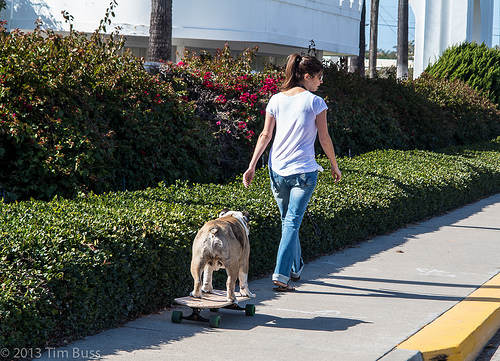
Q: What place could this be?
A: It is a pavement.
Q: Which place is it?
A: It is a pavement.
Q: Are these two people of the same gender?
A: Yes, all the people are female.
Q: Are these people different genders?
A: No, all the people are female.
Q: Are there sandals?
A: Yes, there are sandals.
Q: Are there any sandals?
A: Yes, there are sandals.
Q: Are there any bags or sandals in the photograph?
A: Yes, there are sandals.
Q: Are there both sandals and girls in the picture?
A: Yes, there are both sandals and a girl.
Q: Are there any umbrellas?
A: No, there are no umbrellas.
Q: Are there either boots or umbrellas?
A: No, there are no umbrellas or boots.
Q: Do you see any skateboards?
A: Yes, there is a skateboard.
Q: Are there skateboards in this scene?
A: Yes, there is a skateboard.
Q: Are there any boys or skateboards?
A: Yes, there is a skateboard.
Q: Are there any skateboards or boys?
A: Yes, there is a skateboard.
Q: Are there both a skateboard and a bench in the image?
A: No, there is a skateboard but no benches.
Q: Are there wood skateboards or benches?
A: Yes, there is a wood skateboard.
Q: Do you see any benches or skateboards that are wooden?
A: Yes, the skateboard is wooden.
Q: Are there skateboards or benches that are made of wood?
A: Yes, the skateboard is made of wood.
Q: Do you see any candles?
A: No, there are no candles.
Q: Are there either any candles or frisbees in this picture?
A: No, there are no candles or frisbees.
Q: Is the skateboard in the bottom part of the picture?
A: Yes, the skateboard is in the bottom of the image.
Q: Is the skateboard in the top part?
A: No, the skateboard is in the bottom of the image.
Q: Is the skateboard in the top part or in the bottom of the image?
A: The skateboard is in the bottom of the image.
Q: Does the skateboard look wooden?
A: Yes, the skateboard is wooden.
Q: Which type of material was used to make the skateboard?
A: The skateboard is made of wood.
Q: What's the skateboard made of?
A: The skateboard is made of wood.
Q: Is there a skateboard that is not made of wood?
A: No, there is a skateboard but it is made of wood.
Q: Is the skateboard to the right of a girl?
A: No, the skateboard is to the left of a girl.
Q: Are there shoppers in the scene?
A: No, there are no shoppers.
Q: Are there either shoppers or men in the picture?
A: No, there are no shoppers or men.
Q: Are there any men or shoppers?
A: No, there are no shoppers or men.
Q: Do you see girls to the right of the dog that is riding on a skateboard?
A: Yes, there is a girl to the right of the dog.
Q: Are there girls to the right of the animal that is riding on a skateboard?
A: Yes, there is a girl to the right of the dog.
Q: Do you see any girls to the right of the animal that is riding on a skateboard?
A: Yes, there is a girl to the right of the dog.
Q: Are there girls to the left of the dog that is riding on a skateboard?
A: No, the girl is to the right of the dog.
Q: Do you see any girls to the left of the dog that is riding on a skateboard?
A: No, the girl is to the right of the dog.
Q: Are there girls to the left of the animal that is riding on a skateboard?
A: No, the girl is to the right of the dog.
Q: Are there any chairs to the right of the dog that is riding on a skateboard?
A: No, there is a girl to the right of the dog.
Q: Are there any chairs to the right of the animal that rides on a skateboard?
A: No, there is a girl to the right of the dog.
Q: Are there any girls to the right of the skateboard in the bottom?
A: Yes, there is a girl to the right of the skateboard.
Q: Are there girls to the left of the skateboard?
A: No, the girl is to the right of the skateboard.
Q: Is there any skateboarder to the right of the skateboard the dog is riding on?
A: No, there is a girl to the right of the skateboard.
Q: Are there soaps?
A: No, there are no soaps.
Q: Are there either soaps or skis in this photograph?
A: No, there are no soaps or skis.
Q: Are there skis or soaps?
A: No, there are no soaps or skis.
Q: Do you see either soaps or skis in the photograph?
A: No, there are no soaps or skis.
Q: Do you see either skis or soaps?
A: No, there are no soaps or skis.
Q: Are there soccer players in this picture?
A: No, there are no soccer players.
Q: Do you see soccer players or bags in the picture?
A: No, there are no soccer players or bags.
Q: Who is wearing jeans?
A: The girl is wearing jeans.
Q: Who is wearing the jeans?
A: The girl is wearing jeans.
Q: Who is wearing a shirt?
A: The girl is wearing a shirt.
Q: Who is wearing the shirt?
A: The girl is wearing a shirt.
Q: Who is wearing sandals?
A: The girl is wearing sandals.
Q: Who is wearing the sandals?
A: The girl is wearing sandals.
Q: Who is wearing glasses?
A: The girl is wearing glasses.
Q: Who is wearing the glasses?
A: The girl is wearing glasses.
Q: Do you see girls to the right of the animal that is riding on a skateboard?
A: Yes, there is a girl to the right of the dog.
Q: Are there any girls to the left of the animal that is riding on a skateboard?
A: No, the girl is to the right of the dog.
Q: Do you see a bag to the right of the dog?
A: No, there is a girl to the right of the dog.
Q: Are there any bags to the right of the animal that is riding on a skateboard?
A: No, there is a girl to the right of the dog.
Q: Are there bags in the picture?
A: No, there are no bags.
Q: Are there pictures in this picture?
A: No, there are no pictures.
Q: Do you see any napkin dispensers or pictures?
A: No, there are no pictures or napkin dispensers.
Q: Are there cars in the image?
A: No, there are no cars.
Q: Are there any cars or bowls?
A: No, there are no cars or bowls.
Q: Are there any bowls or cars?
A: No, there are no cars or bowls.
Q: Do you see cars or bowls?
A: No, there are no cars or bowls.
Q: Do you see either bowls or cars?
A: No, there are no cars or bowls.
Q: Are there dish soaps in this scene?
A: No, there are no dish soaps.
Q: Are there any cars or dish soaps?
A: No, there are no dish soaps or cars.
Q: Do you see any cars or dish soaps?
A: No, there are no dish soaps or cars.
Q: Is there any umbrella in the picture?
A: No, there are no umbrellas.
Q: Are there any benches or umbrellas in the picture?
A: No, there are no umbrellas or benches.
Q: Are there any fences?
A: No, there are no fences.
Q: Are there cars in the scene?
A: No, there are no cars.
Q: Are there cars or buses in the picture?
A: No, there are no cars or buses.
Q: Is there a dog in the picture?
A: Yes, there is a dog.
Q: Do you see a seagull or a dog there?
A: Yes, there is a dog.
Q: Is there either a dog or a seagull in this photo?
A: Yes, there is a dog.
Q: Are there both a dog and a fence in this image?
A: No, there is a dog but no fences.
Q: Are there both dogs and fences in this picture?
A: No, there is a dog but no fences.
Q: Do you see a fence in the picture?
A: No, there are no fences.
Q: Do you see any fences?
A: No, there are no fences.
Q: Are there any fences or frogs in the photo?
A: No, there are no fences or frogs.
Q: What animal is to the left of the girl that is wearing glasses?
A: The animal is a dog.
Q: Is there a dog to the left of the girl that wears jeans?
A: Yes, there is a dog to the left of the girl.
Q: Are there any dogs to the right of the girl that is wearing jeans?
A: No, the dog is to the left of the girl.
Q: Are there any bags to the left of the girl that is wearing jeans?
A: No, there is a dog to the left of the girl.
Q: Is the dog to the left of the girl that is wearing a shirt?
A: Yes, the dog is to the left of the girl.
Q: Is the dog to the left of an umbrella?
A: No, the dog is to the left of the girl.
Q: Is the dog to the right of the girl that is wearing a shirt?
A: No, the dog is to the left of the girl.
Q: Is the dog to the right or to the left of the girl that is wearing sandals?
A: The dog is to the left of the girl.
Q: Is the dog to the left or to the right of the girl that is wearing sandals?
A: The dog is to the left of the girl.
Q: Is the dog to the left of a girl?
A: Yes, the dog is to the left of a girl.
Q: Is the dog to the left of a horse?
A: No, the dog is to the left of a girl.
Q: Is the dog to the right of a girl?
A: No, the dog is to the left of a girl.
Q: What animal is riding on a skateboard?
A: The dog is riding on a skateboard.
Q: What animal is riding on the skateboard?
A: The dog is riding on a skateboard.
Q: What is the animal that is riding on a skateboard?
A: The animal is a dog.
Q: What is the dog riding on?
A: The dog is riding on a skateboard.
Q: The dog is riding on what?
A: The dog is riding on a skateboard.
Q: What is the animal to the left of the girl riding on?
A: The dog is riding on a skateboard.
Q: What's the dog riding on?
A: The dog is riding on a skateboard.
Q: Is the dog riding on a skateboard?
A: Yes, the dog is riding on a skateboard.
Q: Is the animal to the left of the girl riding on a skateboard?
A: Yes, the dog is riding on a skateboard.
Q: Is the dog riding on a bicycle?
A: No, the dog is riding on a skateboard.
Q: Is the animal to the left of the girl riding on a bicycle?
A: No, the dog is riding on a skateboard.